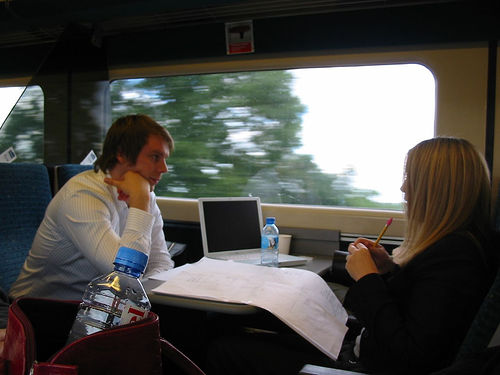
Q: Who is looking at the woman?
A: A man.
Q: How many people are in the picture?
A: Two.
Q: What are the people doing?
A: Talking.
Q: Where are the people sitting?
A: On a train.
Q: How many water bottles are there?
A: Two.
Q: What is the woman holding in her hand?
A: A pencil.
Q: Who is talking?
A: The woman.